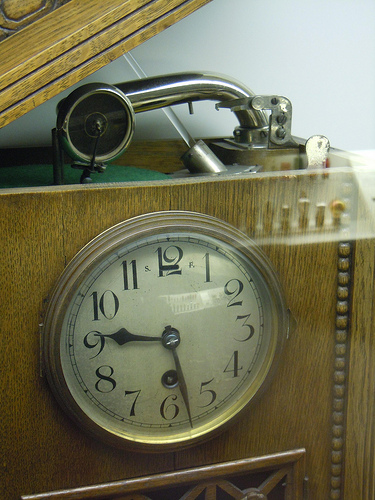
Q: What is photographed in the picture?
A: A stereo.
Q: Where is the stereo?
A: In front of the wall.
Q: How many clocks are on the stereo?
A: One.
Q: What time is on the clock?
A: 9:28.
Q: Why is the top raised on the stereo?
A: To show the needle.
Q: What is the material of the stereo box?
A: Wood.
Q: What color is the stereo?
A: Brown.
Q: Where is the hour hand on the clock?
A: Nine.